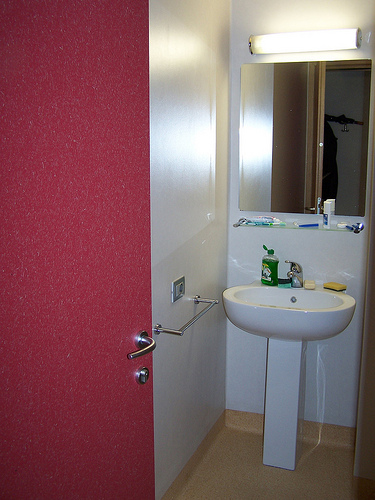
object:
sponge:
[323, 281, 347, 290]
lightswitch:
[171, 276, 185, 303]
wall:
[227, 34, 238, 283]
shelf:
[233, 218, 364, 233]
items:
[233, 199, 364, 233]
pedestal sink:
[221, 280, 355, 471]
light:
[247, 29, 360, 54]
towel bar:
[154, 295, 219, 336]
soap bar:
[303, 279, 316, 289]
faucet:
[285, 260, 303, 288]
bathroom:
[0, 0, 375, 499]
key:
[136, 366, 149, 385]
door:
[0, 1, 156, 499]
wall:
[149, 0, 229, 499]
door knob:
[128, 336, 157, 359]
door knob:
[305, 207, 315, 211]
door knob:
[318, 204, 324, 210]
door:
[310, 61, 325, 214]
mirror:
[238, 66, 371, 219]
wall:
[147, 2, 374, 499]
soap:
[261, 245, 279, 286]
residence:
[2, 3, 375, 499]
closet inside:
[270, 63, 372, 216]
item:
[323, 201, 331, 230]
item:
[294, 222, 319, 227]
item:
[233, 216, 286, 228]